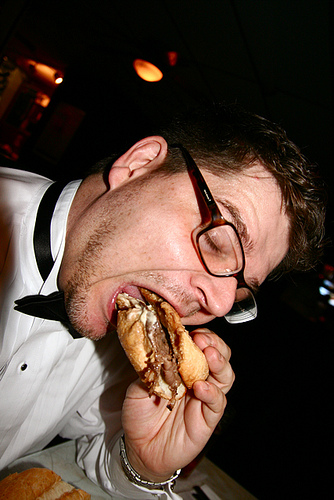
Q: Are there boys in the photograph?
A: No, there are no boys.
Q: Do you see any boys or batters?
A: No, there are no boys or batters.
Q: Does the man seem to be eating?
A: Yes, the man is eating.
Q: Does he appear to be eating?
A: Yes, the man is eating.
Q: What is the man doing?
A: The man is eating.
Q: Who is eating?
A: The man is eating.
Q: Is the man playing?
A: No, the man is eating.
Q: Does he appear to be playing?
A: No, the man is eating.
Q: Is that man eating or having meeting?
A: The man is eating.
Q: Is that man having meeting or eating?
A: The man is eating.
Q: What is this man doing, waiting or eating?
A: The man is eating.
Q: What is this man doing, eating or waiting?
A: The man is eating.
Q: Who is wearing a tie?
A: The man is wearing a tie.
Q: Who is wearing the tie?
A: The man is wearing a tie.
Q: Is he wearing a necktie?
A: Yes, the man is wearing a necktie.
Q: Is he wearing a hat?
A: No, the man is wearing a necktie.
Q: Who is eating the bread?
A: The man is eating the bread.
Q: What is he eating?
A: The man is eating a bread.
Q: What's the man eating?
A: The man is eating a bread.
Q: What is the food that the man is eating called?
A: The food is a bread.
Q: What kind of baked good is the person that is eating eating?
A: The man is eating a bread.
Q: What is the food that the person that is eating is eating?
A: The food is a bread.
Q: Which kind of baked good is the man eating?
A: The man is eating a bread.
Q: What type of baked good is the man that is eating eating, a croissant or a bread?
A: The man is eating a bread.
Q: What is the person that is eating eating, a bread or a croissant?
A: The man is eating a bread.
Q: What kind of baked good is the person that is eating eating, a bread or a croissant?
A: The man is eating a bread.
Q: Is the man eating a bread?
A: Yes, the man is eating a bread.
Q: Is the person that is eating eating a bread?
A: Yes, the man is eating a bread.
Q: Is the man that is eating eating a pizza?
A: No, the man is eating a bread.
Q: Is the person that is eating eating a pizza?
A: No, the man is eating a bread.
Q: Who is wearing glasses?
A: The man is wearing glasses.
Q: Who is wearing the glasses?
A: The man is wearing glasses.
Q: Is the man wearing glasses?
A: Yes, the man is wearing glasses.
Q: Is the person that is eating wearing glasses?
A: Yes, the man is wearing glasses.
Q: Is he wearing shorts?
A: No, the man is wearing glasses.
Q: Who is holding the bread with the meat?
A: The man is holding the bread.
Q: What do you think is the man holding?
A: The man is holding the bread.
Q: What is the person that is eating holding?
A: The man is holding the bread.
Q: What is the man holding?
A: The man is holding the bread.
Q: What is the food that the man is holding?
A: The food is a bread.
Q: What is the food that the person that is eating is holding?
A: The food is a bread.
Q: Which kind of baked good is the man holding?
A: The man is holding the bread.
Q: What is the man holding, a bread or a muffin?
A: The man is holding a bread.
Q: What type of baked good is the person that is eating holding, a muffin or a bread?
A: The man is holding a bread.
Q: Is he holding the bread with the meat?
A: Yes, the man is holding the bread.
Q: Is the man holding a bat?
A: No, the man is holding the bread.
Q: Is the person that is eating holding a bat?
A: No, the man is holding the bread.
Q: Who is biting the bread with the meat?
A: The man is biting the bread.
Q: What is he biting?
A: The man is biting the bread.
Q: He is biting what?
A: The man is biting the bread.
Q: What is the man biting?
A: The man is biting the bread.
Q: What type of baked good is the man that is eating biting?
A: The man is biting the bread.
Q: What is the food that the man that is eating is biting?
A: The food is a bread.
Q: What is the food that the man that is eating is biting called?
A: The food is a bread.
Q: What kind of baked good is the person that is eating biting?
A: The man is biting the bread.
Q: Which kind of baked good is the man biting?
A: The man is biting the bread.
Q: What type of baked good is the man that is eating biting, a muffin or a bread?
A: The man is biting a bread.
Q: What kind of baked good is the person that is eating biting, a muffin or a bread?
A: The man is biting a bread.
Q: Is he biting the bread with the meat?
A: Yes, the man is biting the bread.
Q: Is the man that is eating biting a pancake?
A: No, the man is biting the bread.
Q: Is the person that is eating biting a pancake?
A: No, the man is biting the bread.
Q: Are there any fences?
A: No, there are no fences.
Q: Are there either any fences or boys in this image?
A: No, there are no fences or boys.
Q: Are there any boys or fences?
A: No, there are no fences or boys.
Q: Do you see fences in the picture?
A: No, there are no fences.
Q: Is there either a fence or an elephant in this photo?
A: No, there are no fences or elephants.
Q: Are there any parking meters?
A: No, there are no parking meters.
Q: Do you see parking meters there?
A: No, there are no parking meters.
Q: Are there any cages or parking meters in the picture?
A: No, there are no parking meters or cages.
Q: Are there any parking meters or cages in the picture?
A: No, there are no parking meters or cages.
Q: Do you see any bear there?
A: No, there are no bears.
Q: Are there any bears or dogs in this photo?
A: No, there are no bears or dogs.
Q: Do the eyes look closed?
A: Yes, the eyes are closed.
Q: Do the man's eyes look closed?
A: Yes, the eyes are closed.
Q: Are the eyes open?
A: No, the eyes are closed.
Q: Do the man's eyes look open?
A: No, the eyes are closed.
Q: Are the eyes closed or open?
A: The eyes are closed.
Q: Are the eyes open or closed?
A: The eyes are closed.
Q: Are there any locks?
A: No, there are no locks.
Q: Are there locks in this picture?
A: No, there are no locks.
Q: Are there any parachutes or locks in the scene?
A: No, there are no locks or parachutes.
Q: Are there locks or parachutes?
A: No, there are no locks or parachutes.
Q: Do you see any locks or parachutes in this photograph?
A: No, there are no locks or parachutes.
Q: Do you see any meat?
A: Yes, there is meat.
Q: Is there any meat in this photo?
A: Yes, there is meat.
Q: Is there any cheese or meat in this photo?
A: Yes, there is meat.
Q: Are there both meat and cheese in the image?
A: No, there is meat but no cheese.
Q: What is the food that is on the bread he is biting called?
A: The food is meat.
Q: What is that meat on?
A: The meat is on the bread.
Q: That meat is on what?
A: The meat is on the bread.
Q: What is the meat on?
A: The meat is on the bread.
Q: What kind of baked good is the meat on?
A: The meat is on the bread.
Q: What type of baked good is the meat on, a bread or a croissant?
A: The meat is on a bread.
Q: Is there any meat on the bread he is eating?
A: Yes, there is meat on the bread.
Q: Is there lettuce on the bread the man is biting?
A: No, there is meat on the bread.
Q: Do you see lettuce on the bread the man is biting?
A: No, there is meat on the bread.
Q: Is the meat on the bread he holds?
A: Yes, the meat is on the bread.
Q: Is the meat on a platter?
A: No, the meat is on the bread.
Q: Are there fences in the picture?
A: No, there are no fences.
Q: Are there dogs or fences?
A: No, there are no fences or dogs.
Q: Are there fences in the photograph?
A: No, there are no fences.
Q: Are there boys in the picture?
A: No, there are no boys.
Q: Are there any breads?
A: Yes, there is a bread.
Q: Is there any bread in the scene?
A: Yes, there is a bread.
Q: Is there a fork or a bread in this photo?
A: Yes, there is a bread.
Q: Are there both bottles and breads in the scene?
A: No, there is a bread but no bottles.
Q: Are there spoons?
A: No, there are no spoons.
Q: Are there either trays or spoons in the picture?
A: No, there are no spoons or trays.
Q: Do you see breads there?
A: Yes, there is a bread.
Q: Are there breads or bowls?
A: Yes, there is a bread.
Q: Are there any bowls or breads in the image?
A: Yes, there is a bread.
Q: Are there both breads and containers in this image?
A: No, there is a bread but no containers.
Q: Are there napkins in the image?
A: No, there are no napkins.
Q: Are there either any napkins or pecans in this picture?
A: No, there are no napkins or pecans.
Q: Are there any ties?
A: Yes, there is a tie.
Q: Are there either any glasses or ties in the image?
A: Yes, there is a tie.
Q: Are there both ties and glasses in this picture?
A: Yes, there are both a tie and glasses.